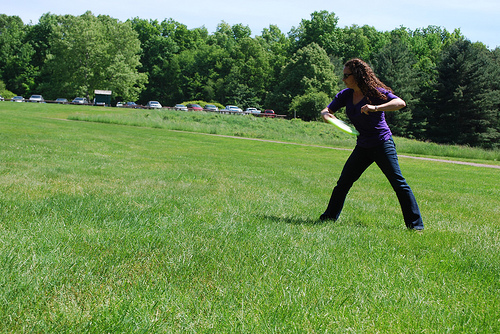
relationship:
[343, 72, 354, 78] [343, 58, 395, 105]
glasses has curly hair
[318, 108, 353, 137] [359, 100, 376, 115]
frisbee in hand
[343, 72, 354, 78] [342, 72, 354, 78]
glasses wearing glasses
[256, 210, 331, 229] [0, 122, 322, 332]
shadow on grass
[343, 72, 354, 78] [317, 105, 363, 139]
glasses preparing to throw frisbee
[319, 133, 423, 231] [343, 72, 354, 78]
jeans on glasses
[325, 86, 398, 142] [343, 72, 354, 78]
purple shirt on glasses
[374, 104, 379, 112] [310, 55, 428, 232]
watch on woman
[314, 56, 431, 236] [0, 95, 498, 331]
girl standing in a field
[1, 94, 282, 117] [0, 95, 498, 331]
cars parked near field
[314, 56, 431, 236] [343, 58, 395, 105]
girl with curly hair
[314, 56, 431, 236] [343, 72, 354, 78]
girl wearing glasses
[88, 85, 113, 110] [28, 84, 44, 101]
shed amidst car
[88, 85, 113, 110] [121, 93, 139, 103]
shed amidst car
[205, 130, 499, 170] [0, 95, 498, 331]
path through field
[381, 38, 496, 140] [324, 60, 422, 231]
pine trees behind girl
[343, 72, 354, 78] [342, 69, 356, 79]
glasses has glasses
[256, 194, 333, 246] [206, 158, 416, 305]
shadow on ground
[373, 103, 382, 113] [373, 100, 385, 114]
watch on wrist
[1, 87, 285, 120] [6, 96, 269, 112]
cars in parking lot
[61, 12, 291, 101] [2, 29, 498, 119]
green trees on background